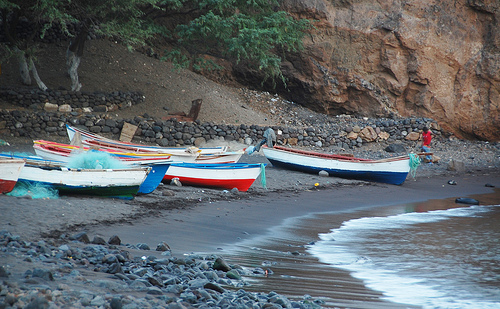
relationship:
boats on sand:
[1, 128, 440, 200] [1, 193, 116, 230]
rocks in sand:
[57, 234, 228, 308] [1, 193, 116, 230]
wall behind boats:
[4, 105, 444, 150] [1, 128, 440, 200]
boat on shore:
[263, 140, 413, 185] [114, 178, 499, 262]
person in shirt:
[419, 124, 433, 163] [420, 129, 437, 146]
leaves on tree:
[226, 20, 262, 42] [61, 7, 287, 87]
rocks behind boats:
[6, 88, 143, 111] [1, 128, 440, 200]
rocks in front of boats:
[57, 234, 228, 308] [1, 128, 440, 200]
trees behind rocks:
[6, 5, 309, 98] [57, 234, 228, 308]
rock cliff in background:
[149, 2, 499, 135] [105, 43, 491, 56]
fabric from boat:
[260, 162, 267, 189] [161, 155, 266, 194]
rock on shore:
[69, 230, 92, 246] [114, 178, 499, 262]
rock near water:
[69, 230, 92, 246] [353, 236, 447, 263]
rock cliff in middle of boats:
[152, 0, 500, 143] [1, 128, 440, 200]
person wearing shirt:
[419, 124, 433, 163] [420, 129, 437, 146]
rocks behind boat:
[6, 88, 143, 111] [263, 140, 413, 185]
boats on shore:
[1, 128, 440, 200] [114, 178, 499, 262]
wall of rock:
[4, 105, 444, 150] [69, 230, 92, 246]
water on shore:
[353, 236, 447, 263] [114, 178, 499, 262]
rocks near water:
[57, 234, 228, 308] [353, 236, 447, 263]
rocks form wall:
[57, 234, 228, 308] [4, 105, 444, 150]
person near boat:
[419, 124, 433, 163] [263, 140, 413, 185]